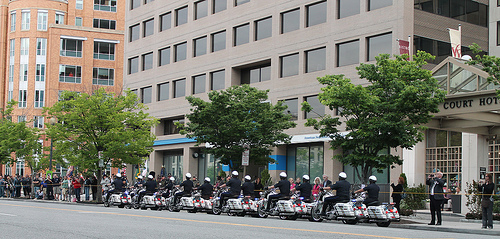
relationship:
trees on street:
[52, 94, 287, 177] [28, 203, 265, 238]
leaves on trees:
[104, 109, 140, 141] [52, 94, 287, 177]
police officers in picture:
[206, 171, 341, 194] [35, 18, 485, 222]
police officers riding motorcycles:
[206, 171, 341, 194] [196, 192, 390, 220]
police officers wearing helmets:
[206, 171, 341, 194] [278, 170, 311, 178]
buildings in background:
[14, 17, 353, 162] [15, 11, 484, 67]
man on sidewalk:
[421, 170, 445, 236] [407, 198, 499, 227]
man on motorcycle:
[332, 172, 350, 201] [312, 200, 367, 223]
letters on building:
[438, 97, 499, 111] [249, 10, 500, 174]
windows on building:
[134, 9, 228, 60] [249, 10, 500, 174]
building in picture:
[249, 10, 500, 174] [35, 18, 485, 222]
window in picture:
[207, 27, 229, 54] [35, 18, 485, 222]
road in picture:
[29, 197, 176, 237] [35, 18, 485, 222]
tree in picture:
[342, 71, 432, 212] [35, 18, 485, 222]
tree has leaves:
[342, 71, 432, 212] [104, 109, 140, 141]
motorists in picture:
[339, 171, 374, 202] [35, 18, 485, 222]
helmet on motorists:
[361, 171, 378, 184] [339, 171, 374, 202]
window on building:
[207, 27, 229, 54] [249, 10, 500, 174]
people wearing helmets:
[238, 172, 391, 210] [278, 170, 311, 178]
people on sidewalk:
[22, 171, 99, 203] [407, 198, 499, 227]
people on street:
[22, 171, 99, 203] [28, 203, 265, 238]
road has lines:
[29, 197, 176, 237] [49, 202, 129, 224]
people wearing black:
[238, 172, 391, 210] [333, 186, 347, 199]